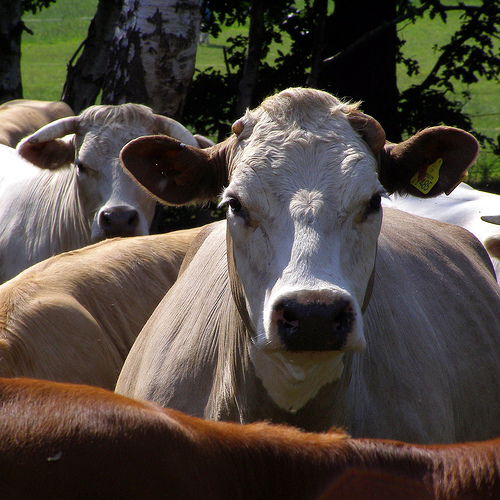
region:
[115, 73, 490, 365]
the head of a cow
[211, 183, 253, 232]
the eye of a cow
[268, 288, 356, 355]
the nose of a cow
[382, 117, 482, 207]
the ear of a cow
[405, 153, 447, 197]
a yellow tag on the cow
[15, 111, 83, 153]
the horn of a cow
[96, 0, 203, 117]
a white tree trunk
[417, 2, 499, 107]
the leaves of a tree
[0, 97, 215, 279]
a white cow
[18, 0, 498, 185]
a grassy green field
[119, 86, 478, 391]
cow looking at camera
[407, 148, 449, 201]
yellow tag in cow ear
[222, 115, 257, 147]
stump of removed horn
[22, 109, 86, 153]
horn on cow head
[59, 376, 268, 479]
brown fur on cow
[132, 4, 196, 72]
white bark on birch tree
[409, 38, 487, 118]
silhouette of tree leaves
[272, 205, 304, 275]
shadow on cow's face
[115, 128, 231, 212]
brown ear on cow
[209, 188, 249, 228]
long eyeleashes on eye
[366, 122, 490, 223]
Yellow tracking tag in ear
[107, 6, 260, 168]
Birch bark behind the cows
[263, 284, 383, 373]
Big wet cow nose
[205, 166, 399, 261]
Soulful cow eyes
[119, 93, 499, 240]
Funny ears sticking out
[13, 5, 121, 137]
Green grass in the distance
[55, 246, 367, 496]
Brown cow and tan cow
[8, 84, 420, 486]
A bunch of cows together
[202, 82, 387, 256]
Soft hair on head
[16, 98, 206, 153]
Horns on head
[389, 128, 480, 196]
an ear of a cow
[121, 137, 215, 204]
an ear of a cow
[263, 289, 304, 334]
a nostril of a nose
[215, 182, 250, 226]
an eye of a cow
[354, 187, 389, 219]
an eye of a cow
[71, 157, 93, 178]
an eye of a cow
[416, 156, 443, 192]
a tag in the ear of a cow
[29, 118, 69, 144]
a horn of a cow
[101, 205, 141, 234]
a nose of a cow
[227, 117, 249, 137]
a horn nub of a cow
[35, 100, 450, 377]
Two cows are facing the camera.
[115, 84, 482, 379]
The cow has a head.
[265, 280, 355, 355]
The cow has a nose.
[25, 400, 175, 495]
Part of a brown cow.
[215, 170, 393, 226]
The cow has two eyes.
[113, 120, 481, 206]
The cow has two ears.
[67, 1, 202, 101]
The trunk of a tree.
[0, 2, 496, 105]
Trees in the background.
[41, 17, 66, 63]
Grass in the background.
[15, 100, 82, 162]
A cow with a horn.